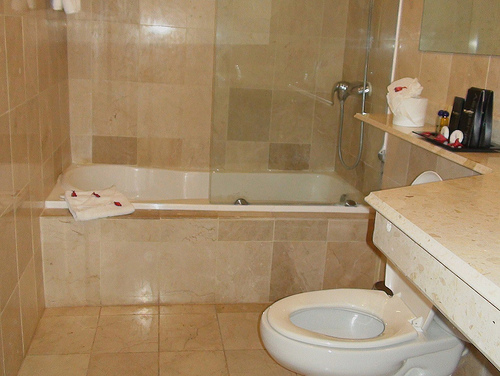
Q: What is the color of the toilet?
A: White.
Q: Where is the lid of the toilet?
A: Up.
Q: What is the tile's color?
A: Light brown.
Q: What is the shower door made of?
A: Clear glass.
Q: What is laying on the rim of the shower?
A: A towel.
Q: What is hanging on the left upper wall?
A: A towel.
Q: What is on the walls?
A: Tile.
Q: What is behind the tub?
A: Tan tile.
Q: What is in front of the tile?
A: Tan marble tile.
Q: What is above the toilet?
A: Marble shelf.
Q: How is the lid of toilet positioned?
A: Open.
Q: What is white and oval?
A: Toilet seat.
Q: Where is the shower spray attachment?
A: On the wall.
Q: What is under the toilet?
A: Tan tile floor.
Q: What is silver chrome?
A: Shower fixture.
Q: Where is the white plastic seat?
A: On top of toilet.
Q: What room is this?
A: Bathroom.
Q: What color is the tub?
A: White.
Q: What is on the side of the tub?
A: Towels.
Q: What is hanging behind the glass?
A: Shower head.